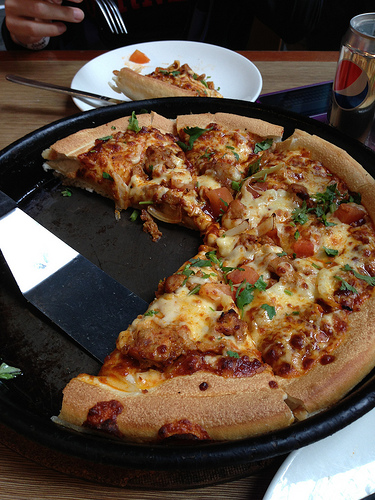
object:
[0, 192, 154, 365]
spatula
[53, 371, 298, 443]
crust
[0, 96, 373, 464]
pan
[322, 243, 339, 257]
basil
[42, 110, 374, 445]
pizza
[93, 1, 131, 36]
fork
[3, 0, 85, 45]
hand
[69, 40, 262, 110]
plate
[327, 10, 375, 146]
can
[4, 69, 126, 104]
knife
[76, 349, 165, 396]
cheese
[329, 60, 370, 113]
logo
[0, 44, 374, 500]
table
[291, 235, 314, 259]
tomatoe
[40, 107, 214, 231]
slice